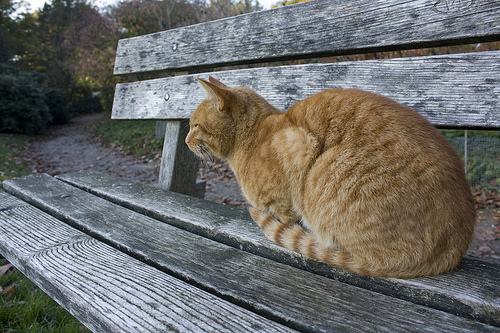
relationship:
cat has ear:
[172, 68, 474, 283] [191, 75, 244, 116]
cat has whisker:
[172, 68, 474, 283] [193, 142, 217, 157]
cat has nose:
[172, 68, 474, 283] [184, 130, 197, 143]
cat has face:
[172, 68, 474, 283] [179, 104, 224, 158]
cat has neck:
[172, 68, 474, 283] [231, 109, 270, 158]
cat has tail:
[172, 68, 474, 283] [249, 205, 329, 260]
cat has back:
[172, 68, 474, 283] [350, 85, 399, 124]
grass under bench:
[7, 283, 47, 328] [54, 31, 210, 308]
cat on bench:
[172, 68, 474, 283] [54, 31, 210, 308]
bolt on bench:
[161, 87, 172, 103] [54, 31, 210, 308]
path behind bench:
[52, 119, 109, 167] [54, 31, 210, 308]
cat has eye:
[172, 68, 474, 283] [192, 122, 202, 130]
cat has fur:
[172, 68, 474, 283] [327, 156, 334, 167]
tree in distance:
[25, 15, 110, 100] [12, 14, 90, 117]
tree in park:
[25, 15, 110, 100] [6, 8, 462, 264]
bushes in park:
[10, 69, 56, 109] [6, 8, 462, 264]